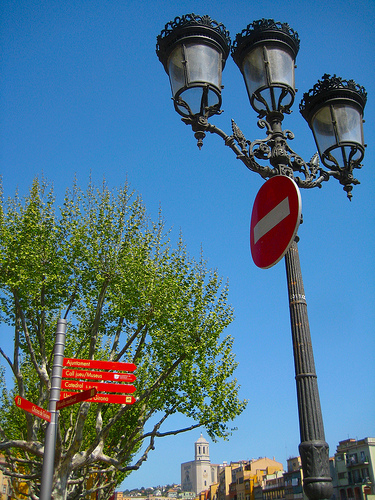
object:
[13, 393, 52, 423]
signs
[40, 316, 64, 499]
pole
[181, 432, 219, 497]
buildings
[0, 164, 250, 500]
tree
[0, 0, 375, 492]
sky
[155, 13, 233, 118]
lights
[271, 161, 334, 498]
post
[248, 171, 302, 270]
sign